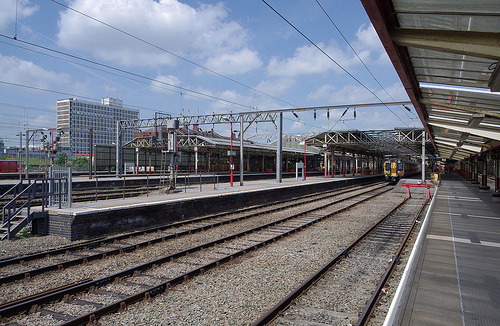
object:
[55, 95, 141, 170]
building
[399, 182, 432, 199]
bench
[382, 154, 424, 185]
train car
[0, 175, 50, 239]
steps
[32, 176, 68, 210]
railing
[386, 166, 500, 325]
platform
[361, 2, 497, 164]
station cover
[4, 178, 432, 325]
train tracks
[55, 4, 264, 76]
clouds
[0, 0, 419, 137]
sky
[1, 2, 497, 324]
train station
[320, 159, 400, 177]
barricade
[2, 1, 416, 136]
cables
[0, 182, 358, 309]
gravel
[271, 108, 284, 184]
pole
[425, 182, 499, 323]
lines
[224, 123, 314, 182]
poles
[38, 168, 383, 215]
platform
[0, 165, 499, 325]
ground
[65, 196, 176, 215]
edge